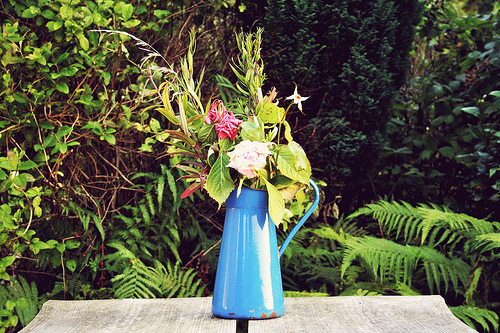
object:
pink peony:
[225, 140, 272, 180]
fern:
[112, 162, 500, 333]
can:
[211, 180, 320, 320]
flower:
[205, 98, 242, 141]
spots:
[213, 311, 277, 319]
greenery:
[0, 0, 500, 333]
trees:
[0, 0, 500, 333]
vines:
[38, 50, 170, 212]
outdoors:
[0, 0, 500, 333]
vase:
[210, 180, 319, 319]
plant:
[0, 0, 500, 333]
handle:
[277, 179, 320, 258]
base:
[213, 316, 282, 333]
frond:
[277, 197, 500, 333]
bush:
[0, 0, 500, 333]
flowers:
[225, 140, 271, 177]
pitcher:
[212, 180, 319, 320]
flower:
[285, 82, 310, 115]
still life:
[89, 16, 310, 228]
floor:
[18, 295, 481, 333]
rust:
[214, 304, 276, 320]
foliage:
[3, 1, 500, 333]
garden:
[0, 0, 500, 331]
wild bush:
[0, 0, 233, 333]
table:
[13, 294, 475, 333]